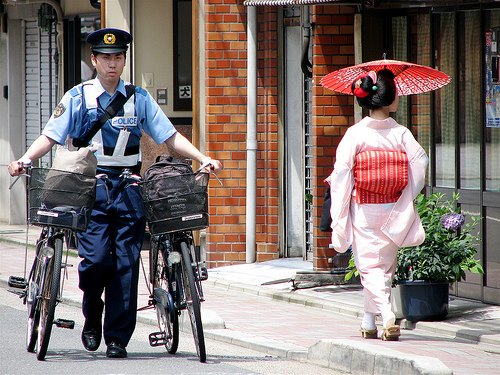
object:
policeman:
[9, 24, 222, 356]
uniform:
[41, 78, 179, 358]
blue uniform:
[41, 77, 180, 165]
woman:
[324, 69, 431, 338]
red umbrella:
[317, 56, 451, 96]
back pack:
[353, 149, 408, 204]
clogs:
[382, 325, 401, 342]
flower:
[444, 215, 465, 231]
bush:
[343, 192, 488, 283]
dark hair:
[349, 69, 397, 109]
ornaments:
[370, 85, 379, 93]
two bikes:
[9, 162, 226, 363]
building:
[189, 0, 355, 270]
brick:
[213, 24, 241, 66]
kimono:
[325, 115, 428, 315]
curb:
[309, 338, 453, 374]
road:
[90, 292, 187, 374]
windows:
[458, 13, 480, 190]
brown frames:
[450, 7, 483, 191]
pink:
[372, 132, 388, 145]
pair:
[360, 325, 404, 341]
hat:
[86, 27, 135, 56]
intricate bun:
[350, 74, 375, 95]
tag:
[114, 115, 141, 128]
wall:
[210, 7, 277, 267]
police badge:
[53, 103, 68, 119]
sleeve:
[40, 91, 75, 147]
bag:
[40, 145, 98, 202]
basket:
[27, 166, 97, 231]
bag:
[144, 151, 207, 233]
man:
[9, 28, 223, 358]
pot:
[403, 278, 451, 321]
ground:
[441, 324, 490, 362]